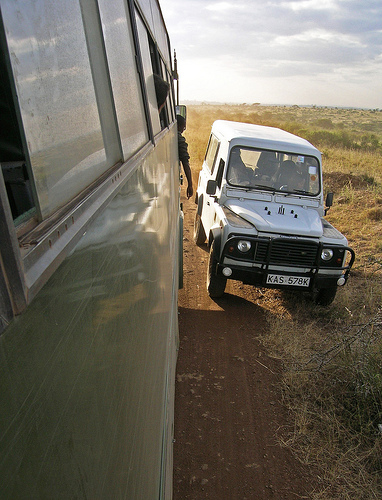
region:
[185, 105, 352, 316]
THE JEEP IS VERY CLOSE TO THE BUS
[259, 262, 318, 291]
THE LICENSE PLATE IS ON THE FRONT OF THE JEEP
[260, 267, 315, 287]
THE JEEP HAS A WHITE LICENSE PLATE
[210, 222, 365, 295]
THE JEEP HAS A BLACK COW CATCHER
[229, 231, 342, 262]
THE JEEP HAS HEADLIGHTS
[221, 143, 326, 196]
THIS IS THE JEEP'S WINDSHIELD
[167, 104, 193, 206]
THE MAN IS LEANING OUT OF THE BUS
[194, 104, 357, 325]
THE JEEP IS WHITE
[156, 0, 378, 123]
THE SKY IS FULL OF HAZY CLOUDS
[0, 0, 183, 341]
THE BUS HAS DIRTY WINDOWS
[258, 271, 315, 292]
License plate on the jeep.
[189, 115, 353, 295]
White jeep parked along the road.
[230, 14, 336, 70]
White clouds in the sky.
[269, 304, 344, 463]
Scrub glass beside the road.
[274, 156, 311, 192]
Man driving a white jeep.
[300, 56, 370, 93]
Blue sky with white clouds.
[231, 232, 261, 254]
Headlights on the jeep.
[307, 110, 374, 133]
Field behind the jeep.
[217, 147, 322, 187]
Windshield on the jeep.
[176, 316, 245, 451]
Not a paved road but a dirt one.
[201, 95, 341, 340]
white truck near bus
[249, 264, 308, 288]
black and white license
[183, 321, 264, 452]
brown and dry road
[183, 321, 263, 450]
dusty and rocky road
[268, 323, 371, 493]
brown grass near truck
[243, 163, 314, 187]
black wipers on truck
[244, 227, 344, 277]
white lights on truck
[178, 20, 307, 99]
grey and white sky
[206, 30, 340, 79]
thick clouds in sky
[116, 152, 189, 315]
green side of bus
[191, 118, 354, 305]
a small white truck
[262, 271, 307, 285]
a white tag on the front of the vehicle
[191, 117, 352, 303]
a man driving a white truck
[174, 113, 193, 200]
a man leaning outside of a truck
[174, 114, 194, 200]
a man in a big truck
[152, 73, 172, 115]
the head of a person on the truck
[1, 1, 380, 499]
three people in trucks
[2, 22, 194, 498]
two men on a big truck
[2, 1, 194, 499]
a truck on a dirt road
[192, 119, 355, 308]
a white truck on the side of a dirt road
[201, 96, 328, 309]
white truck on shoulder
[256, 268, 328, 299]
black and white license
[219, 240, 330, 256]
white lights on truck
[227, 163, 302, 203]
black windshield wipers on truck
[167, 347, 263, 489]
dry and dusty road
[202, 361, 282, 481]
brown and rocky road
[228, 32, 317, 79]
blue and white sky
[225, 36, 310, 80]
puffy clouds in sky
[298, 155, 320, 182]
white stickers on truck